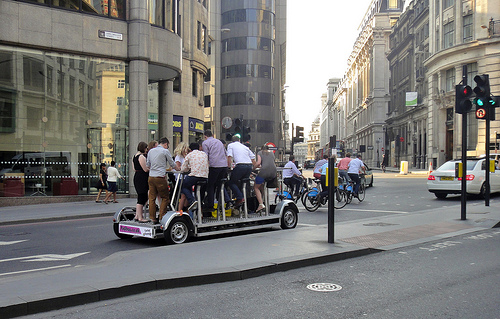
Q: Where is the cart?
A: On the street.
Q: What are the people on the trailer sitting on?
A: Stools.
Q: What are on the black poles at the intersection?
A: Traffic lights.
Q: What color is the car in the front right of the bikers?
A: White.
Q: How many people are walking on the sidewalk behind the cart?
A: Two.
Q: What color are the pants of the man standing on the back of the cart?
A: Brown.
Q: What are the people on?
A: A trailer.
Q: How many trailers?
A: 1.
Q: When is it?
A: Daytime.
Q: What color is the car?
A: White.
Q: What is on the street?
A: People.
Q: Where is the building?
A: Behind the people.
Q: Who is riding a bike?
A: People.